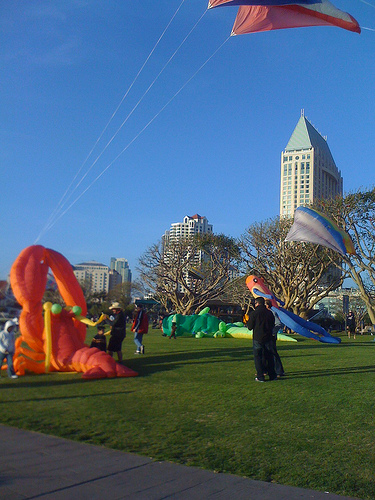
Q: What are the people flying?
A: Kites.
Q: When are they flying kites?
A: Daytime.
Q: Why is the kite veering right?
A: Wind.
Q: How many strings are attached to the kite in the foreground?
A: Three.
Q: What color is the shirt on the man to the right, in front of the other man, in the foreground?
A: Black.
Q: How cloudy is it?
A: Not at all.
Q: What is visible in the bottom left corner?
A: A sidewalk.